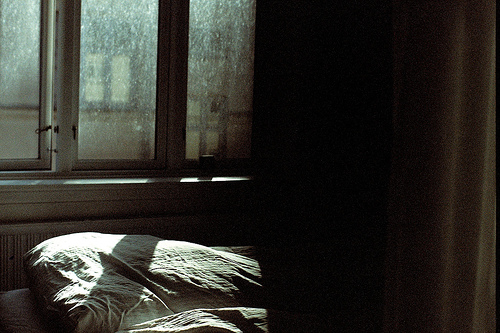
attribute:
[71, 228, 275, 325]
pillow — white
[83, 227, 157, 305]
shadows — black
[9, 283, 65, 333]
bed — dark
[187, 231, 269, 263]
sheet — white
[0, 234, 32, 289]
slats — white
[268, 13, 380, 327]
wall — dark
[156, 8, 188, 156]
windowpane — white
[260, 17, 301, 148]
opposite side — dark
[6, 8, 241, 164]
doors — glass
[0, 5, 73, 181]
pane — glass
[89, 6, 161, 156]
pane — glass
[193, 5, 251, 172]
pane — glass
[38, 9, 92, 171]
trim — white